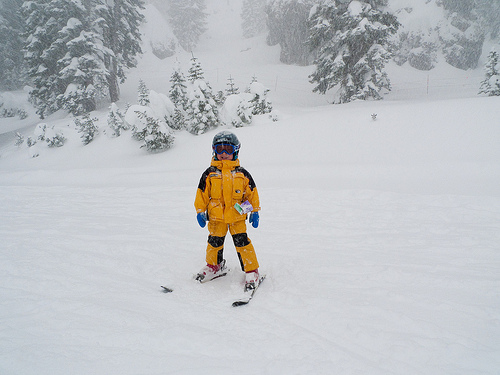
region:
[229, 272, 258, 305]
Child sized snow ski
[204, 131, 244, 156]
A Child blue ski helmet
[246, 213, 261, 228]
A child's blue mitten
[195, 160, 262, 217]
A child's yellow coat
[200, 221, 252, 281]
A child's yellow snow pants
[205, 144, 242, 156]
A pair of blue ski goggles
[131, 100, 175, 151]
snow covered tree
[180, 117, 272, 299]
A child wearing skis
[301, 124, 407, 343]
Powdery snow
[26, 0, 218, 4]
Large snow covered evergreen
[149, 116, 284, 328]
Boy in skis and yellow jacket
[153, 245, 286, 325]
Small pair of skis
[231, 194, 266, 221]
Ski lift ticket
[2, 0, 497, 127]
Trees and saplings covered in snow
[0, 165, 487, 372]
snow covered in ski tracks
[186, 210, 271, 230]
Pair of blue gloves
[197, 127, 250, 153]
Green ski helmet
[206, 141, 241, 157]
Blue ski goggles with orange lenses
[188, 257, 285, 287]
Red ski boots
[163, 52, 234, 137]
Snow covered tree saplings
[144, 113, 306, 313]
There is a boy.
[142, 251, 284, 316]
The boy is wearing skies.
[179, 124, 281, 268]
The boy wears an orange jacket and pants.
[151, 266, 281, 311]
The boy's skies are white.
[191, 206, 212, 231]
The boy's gloves are blue.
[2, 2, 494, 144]
There are trees behind the boy.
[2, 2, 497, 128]
The trees are covered with snow.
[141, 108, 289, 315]
The boy is standing on snow.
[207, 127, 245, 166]
The boy wears a helmet.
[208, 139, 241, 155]
The boy wears blue goggles.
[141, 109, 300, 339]
A small boy skiing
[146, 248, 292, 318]
Children's skis on a boy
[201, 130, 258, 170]
A small boy with a hat and ski goggles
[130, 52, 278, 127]
Snow covered small trees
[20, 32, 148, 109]
A snow covered evergreen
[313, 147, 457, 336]
A snowy field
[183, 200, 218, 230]
A boy's blue mitten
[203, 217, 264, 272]
A boy's yellow and black snow pants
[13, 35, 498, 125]
a snowy grouping of trees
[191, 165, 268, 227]
A boy's yellow ski jacket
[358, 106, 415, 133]
small object in white snow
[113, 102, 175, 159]
snow covered small tree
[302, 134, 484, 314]
large patch of white snow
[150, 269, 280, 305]
pair of skis covered in snow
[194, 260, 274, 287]
small white pair of boy's white snow shoes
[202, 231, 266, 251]
pair of black knee pads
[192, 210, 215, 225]
small blue glove on hand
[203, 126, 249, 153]
boy wearing blue helmet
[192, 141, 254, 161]
boy wearing pair of dark goggles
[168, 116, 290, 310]
boy wearing yellow snow suit